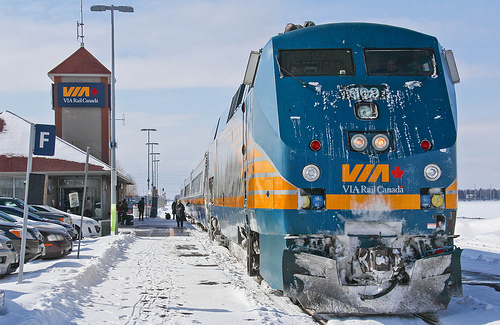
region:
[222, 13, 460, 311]
blue train in snow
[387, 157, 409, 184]
red maple leaf on train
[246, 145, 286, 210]
yellow lines on train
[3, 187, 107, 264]
cars parked in a row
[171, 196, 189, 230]
person walking next to train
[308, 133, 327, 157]
red circular light on train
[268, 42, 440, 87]
two front windows on train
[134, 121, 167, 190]
row of lights on poles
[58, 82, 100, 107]
logo on blue sign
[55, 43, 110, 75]
pointed roof on tower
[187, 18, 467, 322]
blue and yellow train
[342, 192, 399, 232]
snow on front of train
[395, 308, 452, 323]
train tracks in snow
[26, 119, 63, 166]
blue sign with white letter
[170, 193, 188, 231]
person standing next to train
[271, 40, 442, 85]
two windows on front of train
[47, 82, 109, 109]
multi colored sign on tower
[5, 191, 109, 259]
cars parked at train station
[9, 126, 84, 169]
snow on red roof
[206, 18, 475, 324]
Blue and yellow train stopped in front of train terminal.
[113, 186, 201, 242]
People standing in front of train terminal.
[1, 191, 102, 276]
Cars parked in train terminal parking lot.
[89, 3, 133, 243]
Lamp post standing in front of parking lot.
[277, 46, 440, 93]
Front windows on train.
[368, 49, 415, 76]
Engineer inside who drives train.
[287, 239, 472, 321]
Cow catcher on front of train.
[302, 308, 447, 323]
Train tracks sticking out of snow.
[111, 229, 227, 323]
A snow covered walkway.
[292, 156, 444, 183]
Headlights in front of train.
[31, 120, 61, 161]
white letter on blue sign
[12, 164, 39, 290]
metal pole in snow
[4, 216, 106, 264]
front ends of cars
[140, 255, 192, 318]
footprints in snow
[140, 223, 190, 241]
bare pavement surrounded by snow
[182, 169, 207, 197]
windows on side of train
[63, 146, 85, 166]
snow on roof of station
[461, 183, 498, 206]
trees above snowy horizon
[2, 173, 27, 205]
window on train station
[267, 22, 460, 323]
front of a locomotive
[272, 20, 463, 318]
a blue and yellow engine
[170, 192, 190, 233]
a person walking in snow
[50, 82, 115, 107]
a sign for Via Railroad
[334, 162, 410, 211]
writing that identifies the country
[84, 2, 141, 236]
a tall street light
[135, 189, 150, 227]
a person standing in the shade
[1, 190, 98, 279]
a row of parked cars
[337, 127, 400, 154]
two lights that are on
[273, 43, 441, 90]
front windows of the locomotive